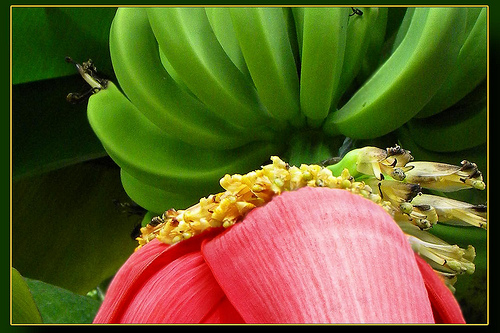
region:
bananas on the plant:
[57, 5, 485, 201]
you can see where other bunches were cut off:
[115, 143, 485, 195]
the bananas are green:
[98, 2, 454, 148]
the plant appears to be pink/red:
[121, 191, 442, 321]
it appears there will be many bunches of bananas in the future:
[68, 30, 478, 325]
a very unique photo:
[46, 5, 495, 332]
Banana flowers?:
[318, 132, 493, 296]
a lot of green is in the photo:
[16, 21, 496, 183]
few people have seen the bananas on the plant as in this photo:
[12, 2, 484, 322]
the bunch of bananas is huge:
[53, 18, 481, 225]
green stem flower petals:
[133, 18, 406, 143]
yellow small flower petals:
[142, 135, 429, 255]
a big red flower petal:
[121, 195, 433, 316]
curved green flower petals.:
[125, 70, 397, 211]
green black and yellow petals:
[340, 135, 466, 196]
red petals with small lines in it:
[222, 195, 417, 315]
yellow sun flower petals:
[124, 125, 356, 270]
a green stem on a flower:
[285, 118, 344, 170]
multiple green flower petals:
[122, 12, 455, 204]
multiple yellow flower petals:
[137, 133, 427, 247]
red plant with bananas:
[63, 0, 479, 323]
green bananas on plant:
[73, 7, 482, 163]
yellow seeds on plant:
[146, 152, 392, 240]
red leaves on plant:
[101, 189, 456, 329]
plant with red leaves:
[47, 6, 479, 331]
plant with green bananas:
[54, 4, 471, 316]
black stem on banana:
[59, 54, 108, 94]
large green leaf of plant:
[14, 11, 131, 298]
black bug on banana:
[347, 5, 364, 21]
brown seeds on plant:
[137, 204, 186, 241]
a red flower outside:
[65, 98, 495, 330]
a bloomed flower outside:
[87, 121, 497, 331]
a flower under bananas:
[64, 26, 431, 331]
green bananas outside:
[41, 1, 482, 218]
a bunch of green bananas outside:
[67, 16, 494, 233]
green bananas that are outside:
[74, 11, 495, 283]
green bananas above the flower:
[71, 22, 492, 327]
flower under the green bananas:
[69, 21, 491, 325]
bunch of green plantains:
[63, 5, 497, 219]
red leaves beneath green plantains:
[93, 194, 467, 329]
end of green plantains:
[62, 54, 112, 102]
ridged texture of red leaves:
[229, 228, 375, 332]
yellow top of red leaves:
[133, 160, 403, 248]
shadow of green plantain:
[38, 8, 113, 87]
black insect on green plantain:
[344, 8, 368, 25]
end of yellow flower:
[358, 142, 414, 182]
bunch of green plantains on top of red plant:
[51, 5, 488, 328]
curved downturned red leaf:
[91, 241, 231, 329]